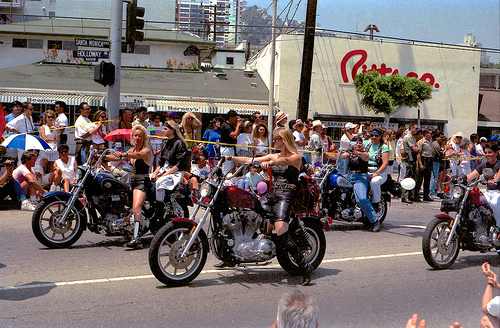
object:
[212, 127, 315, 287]
woman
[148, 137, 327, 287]
motorcycle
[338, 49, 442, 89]
sign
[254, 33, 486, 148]
store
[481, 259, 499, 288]
pair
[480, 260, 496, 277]
hands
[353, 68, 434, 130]
tree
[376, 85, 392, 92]
leaves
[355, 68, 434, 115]
lots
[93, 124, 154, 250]
woman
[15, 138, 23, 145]
blue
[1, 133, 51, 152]
umbrella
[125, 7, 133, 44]
black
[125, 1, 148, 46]
traffic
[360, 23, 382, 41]
object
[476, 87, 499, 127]
roof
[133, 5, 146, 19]
light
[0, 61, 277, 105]
top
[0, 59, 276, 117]
building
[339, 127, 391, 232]
couple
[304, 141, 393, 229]
motorcycle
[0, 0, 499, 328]
background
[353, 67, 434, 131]
small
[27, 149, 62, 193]
person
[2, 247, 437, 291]
line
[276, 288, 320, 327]
back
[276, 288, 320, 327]
head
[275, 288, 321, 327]
hair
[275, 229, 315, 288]
boots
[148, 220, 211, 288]
wheel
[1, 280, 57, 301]
shadow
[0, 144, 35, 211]
someone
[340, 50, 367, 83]
letter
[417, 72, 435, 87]
letter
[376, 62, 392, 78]
letters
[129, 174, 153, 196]
skirt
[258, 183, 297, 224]
skirt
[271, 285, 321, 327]
man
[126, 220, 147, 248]
boots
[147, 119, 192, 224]
person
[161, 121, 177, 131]
bandana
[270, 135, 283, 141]
sunglasses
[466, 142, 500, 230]
woman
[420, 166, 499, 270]
motorcycle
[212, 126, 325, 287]
blonde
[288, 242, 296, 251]
leather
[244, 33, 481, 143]
building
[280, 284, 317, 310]
top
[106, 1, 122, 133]
pole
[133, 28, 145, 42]
street light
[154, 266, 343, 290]
shadow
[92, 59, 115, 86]
street sign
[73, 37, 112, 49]
street sign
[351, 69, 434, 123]
green tree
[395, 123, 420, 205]
audience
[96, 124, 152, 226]
blonde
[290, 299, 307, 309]
balding spot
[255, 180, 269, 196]
balloon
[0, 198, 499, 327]
street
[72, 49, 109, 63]
street-name sign